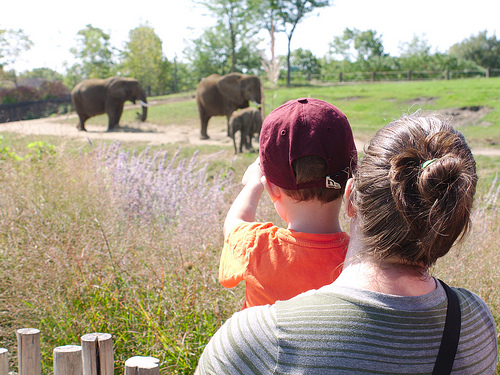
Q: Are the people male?
A: No, they are both male and female.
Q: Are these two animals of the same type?
A: Yes, all the animals are elephants.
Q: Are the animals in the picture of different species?
A: No, all the animals are elephants.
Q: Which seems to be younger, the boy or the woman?
A: The boy is younger than the woman.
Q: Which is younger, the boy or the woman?
A: The boy is younger than the woman.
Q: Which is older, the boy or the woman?
A: The woman is older than the boy.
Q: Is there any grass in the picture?
A: Yes, there is grass.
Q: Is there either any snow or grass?
A: Yes, there is grass.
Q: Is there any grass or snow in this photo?
A: Yes, there is grass.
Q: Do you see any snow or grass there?
A: Yes, there is grass.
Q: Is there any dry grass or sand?
A: Yes, there is dry grass.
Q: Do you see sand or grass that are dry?
A: Yes, the grass is dry.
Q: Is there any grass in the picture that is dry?
A: Yes, there is dry grass.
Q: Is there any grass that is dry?
A: Yes, there is grass that is dry.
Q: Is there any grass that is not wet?
A: Yes, there is dry grass.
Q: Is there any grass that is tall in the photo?
A: Yes, there is tall grass.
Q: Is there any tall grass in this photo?
A: Yes, there is tall grass.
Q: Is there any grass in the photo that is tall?
A: Yes, there is grass that is tall.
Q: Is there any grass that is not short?
A: Yes, there is tall grass.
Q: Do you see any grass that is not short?
A: Yes, there is tall grass.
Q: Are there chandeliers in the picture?
A: No, there are no chandeliers.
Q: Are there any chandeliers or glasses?
A: No, there are no chandeliers or glasses.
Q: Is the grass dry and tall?
A: Yes, the grass is dry and tall.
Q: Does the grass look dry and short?
A: No, the grass is dry but tall.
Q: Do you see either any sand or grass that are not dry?
A: No, there is grass but it is dry.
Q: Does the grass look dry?
A: Yes, the grass is dry.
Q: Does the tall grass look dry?
A: Yes, the grass is dry.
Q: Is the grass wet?
A: No, the grass is dry.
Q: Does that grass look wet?
A: No, the grass is dry.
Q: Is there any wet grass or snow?
A: No, there is grass but it is dry.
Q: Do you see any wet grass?
A: No, there is grass but it is dry.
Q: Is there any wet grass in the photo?
A: No, there is grass but it is dry.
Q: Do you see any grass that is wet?
A: No, there is grass but it is dry.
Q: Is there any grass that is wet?
A: No, there is grass but it is dry.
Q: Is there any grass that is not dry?
A: No, there is grass but it is dry.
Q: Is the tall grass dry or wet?
A: The grass is dry.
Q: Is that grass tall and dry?
A: Yes, the grass is tall and dry.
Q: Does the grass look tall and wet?
A: No, the grass is tall but dry.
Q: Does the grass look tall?
A: Yes, the grass is tall.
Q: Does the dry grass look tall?
A: Yes, the grass is tall.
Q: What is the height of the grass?
A: The grass is tall.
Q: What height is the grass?
A: The grass is tall.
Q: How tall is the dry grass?
A: The grass is tall.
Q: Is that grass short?
A: No, the grass is tall.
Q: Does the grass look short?
A: No, the grass is tall.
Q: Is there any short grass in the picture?
A: No, there is grass but it is tall.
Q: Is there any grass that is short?
A: No, there is grass but it is tall.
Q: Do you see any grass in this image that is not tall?
A: No, there is grass but it is tall.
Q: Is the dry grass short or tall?
A: The grass is tall.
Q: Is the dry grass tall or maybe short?
A: The grass is tall.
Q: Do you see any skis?
A: No, there are no skis.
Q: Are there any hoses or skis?
A: No, there are no skis or hoses.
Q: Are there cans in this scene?
A: No, there are no cans.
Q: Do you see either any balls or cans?
A: No, there are no cans or balls.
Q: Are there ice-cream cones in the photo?
A: No, there are no ice-cream cones.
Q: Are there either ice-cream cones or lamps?
A: No, there are no ice-cream cones or lamps.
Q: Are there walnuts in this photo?
A: No, there are no walnuts.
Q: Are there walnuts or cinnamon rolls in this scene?
A: No, there are no walnuts or cinnamon rolls.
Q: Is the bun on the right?
A: Yes, the bun is on the right of the image.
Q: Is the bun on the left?
A: No, the bun is on the right of the image.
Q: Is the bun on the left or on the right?
A: The bun is on the right of the image.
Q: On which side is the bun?
A: The bun is on the right of the image.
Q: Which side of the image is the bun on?
A: The bun is on the right of the image.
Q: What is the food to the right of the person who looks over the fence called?
A: The food is a bun.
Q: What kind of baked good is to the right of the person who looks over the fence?
A: The food is a bun.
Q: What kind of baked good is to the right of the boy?
A: The food is a bun.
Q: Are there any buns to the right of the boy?
A: Yes, there is a bun to the right of the boy.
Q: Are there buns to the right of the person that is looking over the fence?
A: Yes, there is a bun to the right of the boy.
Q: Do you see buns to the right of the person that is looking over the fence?
A: Yes, there is a bun to the right of the boy.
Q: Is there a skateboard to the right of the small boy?
A: No, there is a bun to the right of the boy.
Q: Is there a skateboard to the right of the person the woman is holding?
A: No, there is a bun to the right of the boy.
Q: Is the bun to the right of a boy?
A: Yes, the bun is to the right of a boy.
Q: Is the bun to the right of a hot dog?
A: No, the bun is to the right of a boy.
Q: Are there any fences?
A: Yes, there is a fence.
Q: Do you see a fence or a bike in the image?
A: Yes, there is a fence.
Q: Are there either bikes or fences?
A: Yes, there is a fence.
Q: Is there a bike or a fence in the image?
A: Yes, there is a fence.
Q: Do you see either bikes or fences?
A: Yes, there is a fence.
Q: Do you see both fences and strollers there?
A: No, there is a fence but no strollers.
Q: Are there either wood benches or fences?
A: Yes, there is a wood fence.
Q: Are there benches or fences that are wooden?
A: Yes, the fence is wooden.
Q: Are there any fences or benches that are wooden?
A: Yes, the fence is wooden.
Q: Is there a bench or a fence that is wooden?
A: Yes, the fence is wooden.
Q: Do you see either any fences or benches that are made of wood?
A: Yes, the fence is made of wood.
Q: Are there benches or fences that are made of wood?
A: Yes, the fence is made of wood.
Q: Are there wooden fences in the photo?
A: Yes, there is a wood fence.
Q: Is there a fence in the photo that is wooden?
A: Yes, there is a fence that is wooden.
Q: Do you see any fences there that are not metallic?
A: Yes, there is a wooden fence.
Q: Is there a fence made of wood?
A: Yes, there is a fence that is made of wood.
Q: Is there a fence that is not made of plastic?
A: Yes, there is a fence that is made of wood.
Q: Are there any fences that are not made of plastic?
A: Yes, there is a fence that is made of wood.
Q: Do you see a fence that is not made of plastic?
A: Yes, there is a fence that is made of wood.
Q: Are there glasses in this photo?
A: No, there are no glasses.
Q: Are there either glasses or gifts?
A: No, there are no glasses or gifts.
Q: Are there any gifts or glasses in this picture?
A: No, there are no glasses or gifts.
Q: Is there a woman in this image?
A: Yes, there is a woman.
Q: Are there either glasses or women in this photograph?
A: Yes, there is a woman.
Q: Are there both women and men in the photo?
A: No, there is a woman but no men.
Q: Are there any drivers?
A: No, there are no drivers.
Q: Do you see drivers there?
A: No, there are no drivers.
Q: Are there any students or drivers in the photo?
A: No, there are no drivers or students.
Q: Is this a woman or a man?
A: This is a woman.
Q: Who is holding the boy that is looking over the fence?
A: The woman is holding the boy.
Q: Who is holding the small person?
A: The woman is holding the boy.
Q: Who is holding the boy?
A: The woman is holding the boy.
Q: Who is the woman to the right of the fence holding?
A: The woman is holding the boy.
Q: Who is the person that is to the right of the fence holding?
A: The woman is holding the boy.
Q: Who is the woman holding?
A: The woman is holding the boy.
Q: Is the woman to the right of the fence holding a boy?
A: Yes, the woman is holding a boy.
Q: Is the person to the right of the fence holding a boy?
A: Yes, the woman is holding a boy.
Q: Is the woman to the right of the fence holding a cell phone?
A: No, the woman is holding a boy.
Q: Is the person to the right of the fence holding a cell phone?
A: No, the woman is holding a boy.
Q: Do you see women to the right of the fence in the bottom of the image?
A: Yes, there is a woman to the right of the fence.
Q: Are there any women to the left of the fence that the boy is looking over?
A: No, the woman is to the right of the fence.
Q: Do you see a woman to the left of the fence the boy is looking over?
A: No, the woman is to the right of the fence.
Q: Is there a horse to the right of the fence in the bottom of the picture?
A: No, there is a woman to the right of the fence.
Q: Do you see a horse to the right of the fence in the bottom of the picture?
A: No, there is a woman to the right of the fence.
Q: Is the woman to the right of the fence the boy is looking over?
A: Yes, the woman is to the right of the fence.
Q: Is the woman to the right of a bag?
A: No, the woman is to the right of the fence.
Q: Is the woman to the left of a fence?
A: No, the woman is to the right of a fence.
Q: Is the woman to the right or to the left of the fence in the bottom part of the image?
A: The woman is to the right of the fence.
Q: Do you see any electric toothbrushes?
A: No, there are no electric toothbrushes.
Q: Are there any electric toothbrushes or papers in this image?
A: No, there are no electric toothbrushes or papers.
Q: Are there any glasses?
A: No, there are no glasses.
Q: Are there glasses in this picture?
A: No, there are no glasses.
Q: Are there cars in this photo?
A: No, there are no cars.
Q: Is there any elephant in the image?
A: Yes, there is an elephant.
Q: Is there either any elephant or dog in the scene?
A: Yes, there is an elephant.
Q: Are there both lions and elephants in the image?
A: No, there is an elephant but no lions.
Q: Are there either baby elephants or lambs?
A: Yes, there is a baby elephant.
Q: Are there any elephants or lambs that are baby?
A: Yes, the elephant is a baby.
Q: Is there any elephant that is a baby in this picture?
A: Yes, there is a baby elephant.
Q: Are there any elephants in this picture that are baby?
A: Yes, there is an elephant that is a baby.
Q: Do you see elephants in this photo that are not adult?
A: Yes, there is an baby elephant.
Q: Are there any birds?
A: No, there are no birds.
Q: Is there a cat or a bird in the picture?
A: No, there are no birds or cats.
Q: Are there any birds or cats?
A: No, there are no birds or cats.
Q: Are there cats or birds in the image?
A: No, there are no birds or cats.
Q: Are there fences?
A: Yes, there is a fence.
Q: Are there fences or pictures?
A: Yes, there is a fence.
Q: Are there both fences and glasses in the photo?
A: No, there is a fence but no glasses.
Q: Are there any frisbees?
A: No, there are no frisbees.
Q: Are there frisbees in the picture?
A: No, there are no frisbees.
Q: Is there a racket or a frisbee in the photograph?
A: No, there are no frisbees or rackets.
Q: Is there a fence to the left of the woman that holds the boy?
A: Yes, there is a fence to the left of the woman.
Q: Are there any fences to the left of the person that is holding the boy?
A: Yes, there is a fence to the left of the woman.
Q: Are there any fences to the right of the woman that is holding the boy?
A: No, the fence is to the left of the woman.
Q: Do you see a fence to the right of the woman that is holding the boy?
A: No, the fence is to the left of the woman.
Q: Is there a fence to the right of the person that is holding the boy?
A: No, the fence is to the left of the woman.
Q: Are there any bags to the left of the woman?
A: No, there is a fence to the left of the woman.